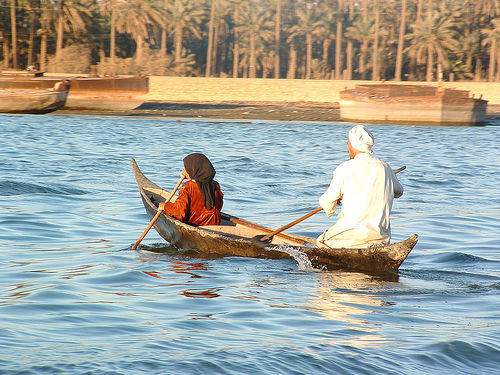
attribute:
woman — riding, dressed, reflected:
[157, 153, 224, 226]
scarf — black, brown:
[183, 153, 217, 209]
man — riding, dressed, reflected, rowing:
[316, 124, 403, 248]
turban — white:
[347, 124, 375, 154]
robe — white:
[317, 152, 403, 247]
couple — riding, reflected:
[157, 124, 404, 249]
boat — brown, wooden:
[131, 158, 417, 266]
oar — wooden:
[131, 173, 186, 249]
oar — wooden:
[260, 165, 405, 240]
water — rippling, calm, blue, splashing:
[0, 113, 499, 374]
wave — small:
[416, 251, 498, 266]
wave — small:
[0, 177, 103, 197]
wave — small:
[210, 155, 263, 165]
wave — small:
[0, 340, 497, 372]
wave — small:
[399, 177, 465, 185]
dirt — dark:
[109, 100, 499, 123]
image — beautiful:
[1, 0, 499, 373]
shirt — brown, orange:
[164, 179, 224, 225]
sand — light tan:
[0, 72, 499, 105]